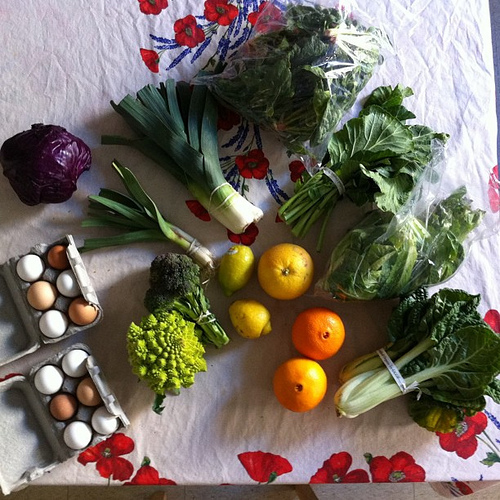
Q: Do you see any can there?
A: No, there are no cans.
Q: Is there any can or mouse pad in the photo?
A: No, there are no cans or mouse pads.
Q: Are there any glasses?
A: No, there are no glasses.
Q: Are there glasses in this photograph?
A: No, there are no glasses.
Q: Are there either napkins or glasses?
A: No, there are no glasses or napkins.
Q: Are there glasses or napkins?
A: No, there are no glasses or napkins.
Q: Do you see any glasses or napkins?
A: No, there are no glasses or napkins.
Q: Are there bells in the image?
A: No, there are no bells.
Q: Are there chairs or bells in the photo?
A: No, there are no bells or chairs.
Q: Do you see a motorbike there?
A: No, there are no motorcycles.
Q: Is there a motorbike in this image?
A: No, there are no motorcycles.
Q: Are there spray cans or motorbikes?
A: No, there are no motorbikes or spray cans.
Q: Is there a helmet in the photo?
A: No, there are no helmets.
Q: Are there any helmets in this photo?
A: No, there are no helmets.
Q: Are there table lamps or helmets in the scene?
A: No, there are no helmets or table lamps.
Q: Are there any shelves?
A: No, there are no shelves.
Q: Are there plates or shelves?
A: No, there are no shelves or plates.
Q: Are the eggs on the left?
A: Yes, the eggs are on the left of the image.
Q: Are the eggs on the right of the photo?
A: No, the eggs are on the left of the image.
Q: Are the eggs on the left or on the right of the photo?
A: The eggs are on the left of the image.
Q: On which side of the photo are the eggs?
A: The eggs are on the left of the image.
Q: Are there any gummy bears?
A: No, there are no gummy bears.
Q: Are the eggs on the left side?
A: Yes, the eggs are on the left of the image.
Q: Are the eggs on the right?
A: No, the eggs are on the left of the image.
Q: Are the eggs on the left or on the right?
A: The eggs are on the left of the image.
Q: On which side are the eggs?
A: The eggs are on the left of the image.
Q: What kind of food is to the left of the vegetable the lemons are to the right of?
A: The food is eggs.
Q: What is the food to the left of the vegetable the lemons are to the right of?
A: The food is eggs.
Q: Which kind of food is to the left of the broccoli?
A: The food is eggs.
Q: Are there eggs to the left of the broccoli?
A: Yes, there are eggs to the left of the broccoli.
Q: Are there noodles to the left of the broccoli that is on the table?
A: No, there are eggs to the left of the broccoli.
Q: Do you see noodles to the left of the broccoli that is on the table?
A: No, there are eggs to the left of the broccoli.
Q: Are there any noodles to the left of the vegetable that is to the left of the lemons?
A: No, there are eggs to the left of the broccoli.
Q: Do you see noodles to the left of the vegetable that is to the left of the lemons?
A: No, there are eggs to the left of the broccoli.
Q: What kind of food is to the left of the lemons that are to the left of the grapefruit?
A: The food is eggs.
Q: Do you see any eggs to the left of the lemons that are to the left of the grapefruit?
A: Yes, there are eggs to the left of the lemons.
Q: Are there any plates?
A: No, there are no plates.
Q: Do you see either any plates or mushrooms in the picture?
A: No, there are no plates or mushrooms.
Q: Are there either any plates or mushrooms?
A: No, there are no plates or mushrooms.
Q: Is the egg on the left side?
A: Yes, the egg is on the left of the image.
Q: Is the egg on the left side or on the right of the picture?
A: The egg is on the left of the image.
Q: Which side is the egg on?
A: The egg is on the left of the image.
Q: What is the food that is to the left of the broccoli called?
A: The food is an egg.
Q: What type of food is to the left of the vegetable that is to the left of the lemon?
A: The food is an egg.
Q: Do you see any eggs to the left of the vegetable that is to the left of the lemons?
A: Yes, there is an egg to the left of the broccoli.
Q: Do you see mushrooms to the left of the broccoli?
A: No, there is an egg to the left of the broccoli.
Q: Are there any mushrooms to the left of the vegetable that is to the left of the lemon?
A: No, there is an egg to the left of the broccoli.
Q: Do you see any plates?
A: No, there are no plates.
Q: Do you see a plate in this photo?
A: No, there are no plates.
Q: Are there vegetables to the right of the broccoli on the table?
A: Yes, there is a vegetable to the right of the broccoli.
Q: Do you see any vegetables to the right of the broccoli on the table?
A: Yes, there is a vegetable to the right of the broccoli.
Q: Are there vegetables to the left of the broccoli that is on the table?
A: No, the vegetable is to the right of the broccoli.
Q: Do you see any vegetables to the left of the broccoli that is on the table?
A: No, the vegetable is to the right of the broccoli.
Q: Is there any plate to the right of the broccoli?
A: No, there is a vegetable to the right of the broccoli.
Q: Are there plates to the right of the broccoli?
A: No, there is a vegetable to the right of the broccoli.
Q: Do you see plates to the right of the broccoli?
A: No, there is a vegetable to the right of the broccoli.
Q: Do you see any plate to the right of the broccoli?
A: No, there is a vegetable to the right of the broccoli.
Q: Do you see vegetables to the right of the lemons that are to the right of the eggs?
A: Yes, there is a vegetable to the right of the lemons.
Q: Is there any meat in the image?
A: No, there is no meat.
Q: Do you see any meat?
A: No, there is no meat.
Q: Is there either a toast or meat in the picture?
A: No, there are no meat or toasts.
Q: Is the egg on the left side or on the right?
A: The egg is on the left of the image.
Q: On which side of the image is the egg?
A: The egg is on the left of the image.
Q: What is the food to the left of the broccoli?
A: The food is an egg.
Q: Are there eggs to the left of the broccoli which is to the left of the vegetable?
A: Yes, there is an egg to the left of the broccoli.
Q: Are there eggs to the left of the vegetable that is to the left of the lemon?
A: Yes, there is an egg to the left of the broccoli.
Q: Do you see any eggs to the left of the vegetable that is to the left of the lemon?
A: Yes, there is an egg to the left of the broccoli.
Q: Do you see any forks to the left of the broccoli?
A: No, there is an egg to the left of the broccoli.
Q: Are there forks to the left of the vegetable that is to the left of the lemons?
A: No, there is an egg to the left of the broccoli.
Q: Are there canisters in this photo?
A: No, there are no canisters.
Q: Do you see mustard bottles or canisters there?
A: No, there are no canisters or mustard bottles.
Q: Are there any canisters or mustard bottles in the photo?
A: No, there are no canisters or mustard bottles.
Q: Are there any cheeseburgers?
A: No, there are no cheeseburgers.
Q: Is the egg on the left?
A: Yes, the egg is on the left of the image.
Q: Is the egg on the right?
A: No, the egg is on the left of the image.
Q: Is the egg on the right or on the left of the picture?
A: The egg is on the left of the image.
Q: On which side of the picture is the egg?
A: The egg is on the left of the image.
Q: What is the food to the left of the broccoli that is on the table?
A: The food is an egg.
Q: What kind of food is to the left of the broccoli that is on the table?
A: The food is an egg.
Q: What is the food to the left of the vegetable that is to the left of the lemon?
A: The food is an egg.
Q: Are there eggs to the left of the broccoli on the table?
A: Yes, there is an egg to the left of the broccoli.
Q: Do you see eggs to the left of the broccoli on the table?
A: Yes, there is an egg to the left of the broccoli.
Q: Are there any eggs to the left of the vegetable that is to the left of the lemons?
A: Yes, there is an egg to the left of the broccoli.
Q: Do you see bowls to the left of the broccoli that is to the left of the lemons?
A: No, there is an egg to the left of the broccoli.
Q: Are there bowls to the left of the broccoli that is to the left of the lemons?
A: No, there is an egg to the left of the broccoli.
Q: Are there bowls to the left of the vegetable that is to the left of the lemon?
A: No, there is an egg to the left of the broccoli.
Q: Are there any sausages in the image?
A: No, there are no sausages.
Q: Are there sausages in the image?
A: No, there are no sausages.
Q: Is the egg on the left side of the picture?
A: Yes, the egg is on the left of the image.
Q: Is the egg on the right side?
A: No, the egg is on the left of the image.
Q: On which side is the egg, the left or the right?
A: The egg is on the left of the image.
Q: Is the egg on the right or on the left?
A: The egg is on the left of the image.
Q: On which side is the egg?
A: The egg is on the left of the image.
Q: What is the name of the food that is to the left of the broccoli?
A: The food is an egg.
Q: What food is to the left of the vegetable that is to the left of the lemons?
A: The food is an egg.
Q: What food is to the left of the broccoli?
A: The food is an egg.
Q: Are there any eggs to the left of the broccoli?
A: Yes, there is an egg to the left of the broccoli.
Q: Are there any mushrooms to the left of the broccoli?
A: No, there is an egg to the left of the broccoli.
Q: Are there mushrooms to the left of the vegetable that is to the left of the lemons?
A: No, there is an egg to the left of the broccoli.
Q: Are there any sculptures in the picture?
A: No, there are no sculptures.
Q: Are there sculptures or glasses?
A: No, there are no sculptures or glasses.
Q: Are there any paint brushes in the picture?
A: No, there are no paint brushes.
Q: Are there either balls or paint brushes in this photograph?
A: No, there are no paint brushes or balls.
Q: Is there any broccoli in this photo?
A: Yes, there is broccoli.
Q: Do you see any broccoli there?
A: Yes, there is broccoli.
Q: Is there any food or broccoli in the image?
A: Yes, there is broccoli.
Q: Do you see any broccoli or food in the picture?
A: Yes, there is broccoli.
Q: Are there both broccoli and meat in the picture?
A: No, there is broccoli but no meat.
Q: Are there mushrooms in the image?
A: No, there are no mushrooms.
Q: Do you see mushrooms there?
A: No, there are no mushrooms.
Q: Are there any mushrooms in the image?
A: No, there are no mushrooms.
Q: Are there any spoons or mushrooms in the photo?
A: No, there are no mushrooms or spoons.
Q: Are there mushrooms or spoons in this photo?
A: No, there are no mushrooms or spoons.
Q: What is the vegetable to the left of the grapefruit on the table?
A: The vegetable is broccoli.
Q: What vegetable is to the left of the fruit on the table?
A: The vegetable is broccoli.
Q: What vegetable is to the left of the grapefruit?
A: The vegetable is broccoli.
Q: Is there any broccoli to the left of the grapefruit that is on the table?
A: Yes, there is broccoli to the left of the grapefruit.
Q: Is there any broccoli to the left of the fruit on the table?
A: Yes, there is broccoli to the left of the grapefruit.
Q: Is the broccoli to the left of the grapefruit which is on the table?
A: Yes, the broccoli is to the left of the grapefruit.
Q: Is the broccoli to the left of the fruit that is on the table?
A: Yes, the broccoli is to the left of the grapefruit.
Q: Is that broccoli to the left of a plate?
A: No, the broccoli is to the left of the grapefruit.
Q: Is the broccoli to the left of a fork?
A: No, the broccoli is to the left of the vegetable.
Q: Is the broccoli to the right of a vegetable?
A: No, the broccoli is to the left of a vegetable.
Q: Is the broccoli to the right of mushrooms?
A: No, the broccoli is to the right of the eggs.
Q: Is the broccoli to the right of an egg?
A: Yes, the broccoli is to the right of an egg.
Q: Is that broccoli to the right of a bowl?
A: No, the broccoli is to the right of an egg.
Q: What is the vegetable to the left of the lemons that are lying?
A: The vegetable is broccoli.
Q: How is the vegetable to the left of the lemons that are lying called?
A: The vegetable is broccoli.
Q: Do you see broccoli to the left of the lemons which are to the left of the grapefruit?
A: Yes, there is broccoli to the left of the lemons.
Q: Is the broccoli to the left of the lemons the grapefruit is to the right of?
A: Yes, the broccoli is to the left of the lemons.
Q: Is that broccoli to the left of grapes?
A: No, the broccoli is to the left of the lemons.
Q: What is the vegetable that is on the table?
A: The vegetable is broccoli.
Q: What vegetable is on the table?
A: The vegetable is broccoli.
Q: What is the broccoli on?
A: The broccoli is on the table.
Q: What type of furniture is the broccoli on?
A: The broccoli is on the table.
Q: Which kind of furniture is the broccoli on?
A: The broccoli is on the table.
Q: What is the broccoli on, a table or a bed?
A: The broccoli is on a table.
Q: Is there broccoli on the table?
A: Yes, there is broccoli on the table.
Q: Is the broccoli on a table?
A: Yes, the broccoli is on a table.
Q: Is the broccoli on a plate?
A: No, the broccoli is on a table.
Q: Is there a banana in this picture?
A: No, there are no bananas.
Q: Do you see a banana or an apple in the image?
A: No, there are no bananas or apples.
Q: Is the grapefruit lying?
A: Yes, the grapefruit is lying.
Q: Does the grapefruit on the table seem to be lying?
A: Yes, the grapefruit is lying.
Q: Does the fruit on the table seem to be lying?
A: Yes, the grapefruit is lying.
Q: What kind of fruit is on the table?
A: The fruit is a grapefruit.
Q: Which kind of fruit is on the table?
A: The fruit is a grapefruit.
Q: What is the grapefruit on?
A: The grapefruit is on the table.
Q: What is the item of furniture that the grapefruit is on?
A: The piece of furniture is a table.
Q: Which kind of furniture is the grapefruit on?
A: The grapefruit is on the table.